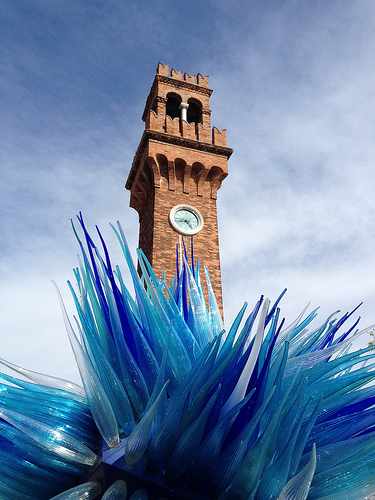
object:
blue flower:
[0, 206, 375, 500]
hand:
[185, 219, 194, 230]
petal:
[50, 276, 120, 452]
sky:
[0, 0, 375, 389]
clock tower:
[123, 58, 235, 330]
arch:
[184, 96, 204, 142]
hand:
[174, 216, 187, 221]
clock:
[167, 203, 205, 237]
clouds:
[0, 0, 375, 387]